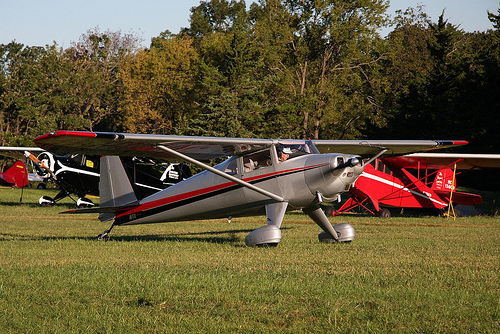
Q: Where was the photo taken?
A: On a field.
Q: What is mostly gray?
A: A plane.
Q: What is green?
A: Grass.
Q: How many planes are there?
A: Three.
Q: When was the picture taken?
A: Daytime.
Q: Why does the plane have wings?
A: To fly.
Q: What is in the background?
A: Trees.